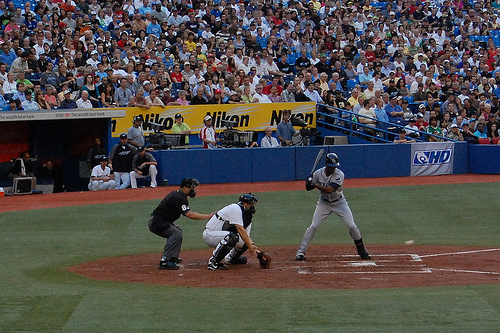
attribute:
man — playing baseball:
[200, 190, 275, 273]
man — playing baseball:
[291, 144, 372, 262]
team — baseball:
[15, 126, 163, 190]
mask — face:
[184, 185, 200, 201]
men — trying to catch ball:
[138, 149, 378, 271]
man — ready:
[288, 135, 377, 271]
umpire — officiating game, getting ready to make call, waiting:
[139, 174, 194, 279]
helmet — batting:
[323, 148, 348, 168]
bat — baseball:
[308, 141, 321, 179]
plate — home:
[346, 255, 378, 271]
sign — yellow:
[116, 106, 326, 127]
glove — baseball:
[259, 247, 272, 271]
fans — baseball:
[0, 1, 497, 143]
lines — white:
[299, 262, 436, 277]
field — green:
[30, 169, 486, 329]